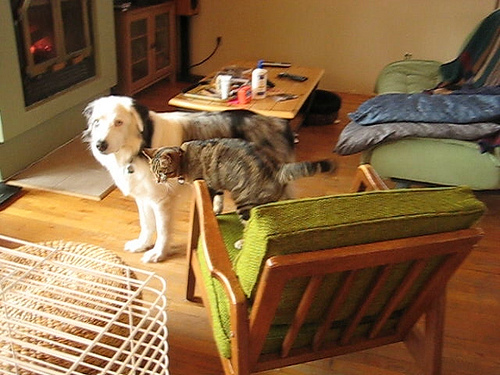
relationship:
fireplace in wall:
[14, 0, 94, 81] [1, 0, 119, 182]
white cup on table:
[214, 72, 233, 104] [167, 61, 324, 115]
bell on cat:
[175, 175, 187, 185] [144, 138, 344, 253]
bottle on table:
[251, 59, 267, 99] [168, 57, 324, 148]